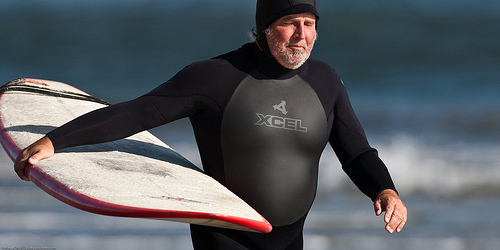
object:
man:
[11, 0, 408, 250]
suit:
[42, 41, 400, 250]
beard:
[270, 50, 313, 70]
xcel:
[249, 112, 309, 135]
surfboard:
[0, 76, 276, 235]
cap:
[254, 0, 320, 30]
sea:
[408, 73, 497, 204]